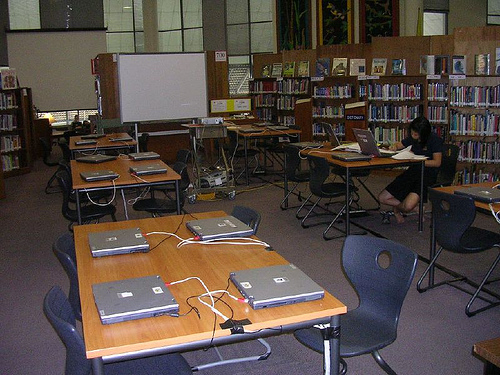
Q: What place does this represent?
A: It represents the library.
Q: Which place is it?
A: It is a library.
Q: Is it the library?
A: Yes, it is the library.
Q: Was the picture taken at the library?
A: Yes, it was taken in the library.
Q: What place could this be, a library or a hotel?
A: It is a library.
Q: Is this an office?
A: No, it is a library.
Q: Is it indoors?
A: Yes, it is indoors.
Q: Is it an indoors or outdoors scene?
A: It is indoors.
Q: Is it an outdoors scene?
A: No, it is indoors.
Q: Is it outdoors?
A: No, it is indoors.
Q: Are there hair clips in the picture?
A: No, there are no hair clips.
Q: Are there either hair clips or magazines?
A: No, there are no hair clips or magazines.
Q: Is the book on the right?
A: Yes, the book is on the right of the image.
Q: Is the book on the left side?
A: No, the book is on the right of the image.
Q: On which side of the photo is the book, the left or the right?
A: The book is on the right of the image.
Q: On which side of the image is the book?
A: The book is on the right of the image.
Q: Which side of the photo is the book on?
A: The book is on the right of the image.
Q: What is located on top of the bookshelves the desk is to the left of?
A: The book is on top of the bookshelves.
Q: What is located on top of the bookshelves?
A: The book is on top of the bookshelves.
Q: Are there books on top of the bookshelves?
A: Yes, there is a book on top of the bookshelves.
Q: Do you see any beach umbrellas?
A: No, there are no beach umbrellas.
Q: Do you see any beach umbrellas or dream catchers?
A: No, there are no beach umbrellas or dream catchers.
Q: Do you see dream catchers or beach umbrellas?
A: No, there are no beach umbrellas or dream catchers.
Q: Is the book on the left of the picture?
A: No, the book is on the right of the image.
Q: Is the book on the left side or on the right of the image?
A: The book is on the right of the image.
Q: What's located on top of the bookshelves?
A: The book is on top of the bookshelves.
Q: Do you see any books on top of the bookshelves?
A: Yes, there is a book on top of the bookshelves.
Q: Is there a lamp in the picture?
A: No, there are no lamps.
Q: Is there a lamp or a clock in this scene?
A: No, there are no lamps or clocks.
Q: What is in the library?
A: The bookshelves are in the library.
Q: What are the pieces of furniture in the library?
A: The pieces of furniture are bookshelves.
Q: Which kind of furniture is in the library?
A: The pieces of furniture are bookshelves.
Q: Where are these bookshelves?
A: The bookshelves are in the library.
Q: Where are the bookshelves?
A: The bookshelves are in the library.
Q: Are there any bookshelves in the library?
A: Yes, there are bookshelves in the library.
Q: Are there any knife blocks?
A: No, there are no knife blocks.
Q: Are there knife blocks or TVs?
A: No, there are no knife blocks or tvs.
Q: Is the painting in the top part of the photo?
A: Yes, the painting is in the top of the image.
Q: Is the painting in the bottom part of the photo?
A: No, the painting is in the top of the image.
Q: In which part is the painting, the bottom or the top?
A: The painting is in the top of the image.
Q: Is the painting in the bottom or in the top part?
A: The painting is in the top of the image.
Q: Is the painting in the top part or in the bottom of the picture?
A: The painting is in the top of the image.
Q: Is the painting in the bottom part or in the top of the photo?
A: The painting is in the top of the image.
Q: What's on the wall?
A: The painting is on the wall.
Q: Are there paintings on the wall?
A: Yes, there is a painting on the wall.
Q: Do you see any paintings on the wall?
A: Yes, there is a painting on the wall.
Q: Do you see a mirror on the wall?
A: No, there is a painting on the wall.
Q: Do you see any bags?
A: No, there are no bags.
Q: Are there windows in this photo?
A: Yes, there is a window.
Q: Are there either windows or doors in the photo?
A: Yes, there is a window.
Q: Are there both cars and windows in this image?
A: No, there is a window but no cars.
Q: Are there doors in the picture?
A: No, there are no doors.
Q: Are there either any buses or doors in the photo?
A: No, there are no doors or buses.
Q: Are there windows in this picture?
A: Yes, there is a window.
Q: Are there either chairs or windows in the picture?
A: Yes, there is a window.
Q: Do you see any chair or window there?
A: Yes, there is a window.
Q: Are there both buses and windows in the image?
A: No, there is a window but no buses.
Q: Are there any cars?
A: No, there are no cars.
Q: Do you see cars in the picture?
A: No, there are no cars.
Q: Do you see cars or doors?
A: No, there are no cars or doors.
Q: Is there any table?
A: Yes, there is a table.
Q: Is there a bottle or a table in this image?
A: Yes, there is a table.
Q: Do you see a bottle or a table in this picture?
A: Yes, there is a table.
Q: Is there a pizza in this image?
A: No, there are no pizzas.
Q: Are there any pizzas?
A: No, there are no pizzas.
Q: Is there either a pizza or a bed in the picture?
A: No, there are no pizzas or beds.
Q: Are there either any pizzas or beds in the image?
A: No, there are no pizzas or beds.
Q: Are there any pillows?
A: No, there are no pillows.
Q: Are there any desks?
A: Yes, there is a desk.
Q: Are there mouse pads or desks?
A: Yes, there is a desk.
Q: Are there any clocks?
A: No, there are no clocks.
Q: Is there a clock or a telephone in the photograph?
A: No, there are no clocks or phones.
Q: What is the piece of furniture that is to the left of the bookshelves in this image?
A: The piece of furniture is a desk.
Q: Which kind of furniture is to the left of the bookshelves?
A: The piece of furniture is a desk.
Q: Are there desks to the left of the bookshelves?
A: Yes, there is a desk to the left of the bookshelves.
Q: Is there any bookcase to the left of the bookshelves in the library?
A: No, there is a desk to the left of the bookshelves.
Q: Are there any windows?
A: Yes, there is a window.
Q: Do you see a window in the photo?
A: Yes, there is a window.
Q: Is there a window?
A: Yes, there is a window.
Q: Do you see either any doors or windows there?
A: Yes, there is a window.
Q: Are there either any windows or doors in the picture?
A: Yes, there is a window.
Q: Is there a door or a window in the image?
A: Yes, there is a window.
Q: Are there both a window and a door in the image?
A: No, there is a window but no doors.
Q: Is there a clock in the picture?
A: No, there are no clocks.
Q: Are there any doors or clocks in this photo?
A: No, there are no clocks or doors.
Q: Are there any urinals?
A: No, there are no urinals.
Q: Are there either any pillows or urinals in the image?
A: No, there are no urinals or pillows.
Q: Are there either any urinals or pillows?
A: No, there are no urinals or pillows.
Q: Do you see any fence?
A: No, there are no fences.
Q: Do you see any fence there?
A: No, there are no fences.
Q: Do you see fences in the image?
A: No, there are no fences.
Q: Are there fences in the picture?
A: No, there are no fences.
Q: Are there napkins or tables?
A: Yes, there is a table.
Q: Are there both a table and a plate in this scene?
A: No, there is a table but no plates.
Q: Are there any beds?
A: No, there are no beds.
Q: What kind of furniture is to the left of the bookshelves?
A: The piece of furniture is a table.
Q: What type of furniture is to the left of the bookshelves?
A: The piece of furniture is a table.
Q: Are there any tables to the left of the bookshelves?
A: Yes, there is a table to the left of the bookshelves.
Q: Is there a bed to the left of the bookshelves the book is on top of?
A: No, there is a table to the left of the bookshelves.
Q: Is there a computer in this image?
A: Yes, there is a computer.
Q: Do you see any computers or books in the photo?
A: Yes, there is a computer.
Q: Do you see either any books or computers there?
A: Yes, there is a computer.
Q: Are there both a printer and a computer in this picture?
A: No, there is a computer but no printers.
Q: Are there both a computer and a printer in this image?
A: No, there is a computer but no printers.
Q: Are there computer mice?
A: No, there are no computer mice.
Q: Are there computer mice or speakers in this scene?
A: No, there are no computer mice or speakers.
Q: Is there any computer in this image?
A: Yes, there is a computer.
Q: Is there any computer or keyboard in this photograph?
A: Yes, there is a computer.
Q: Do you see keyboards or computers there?
A: Yes, there is a computer.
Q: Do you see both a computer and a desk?
A: Yes, there are both a computer and a desk.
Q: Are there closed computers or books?
A: Yes, there is a closed computer.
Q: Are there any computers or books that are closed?
A: Yes, the computer is closed.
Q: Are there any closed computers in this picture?
A: Yes, there is a closed computer.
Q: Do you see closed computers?
A: Yes, there is a closed computer.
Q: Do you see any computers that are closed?
A: Yes, there is a closed computer.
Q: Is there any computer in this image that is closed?
A: Yes, there is a computer that is closed.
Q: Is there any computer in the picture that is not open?
A: Yes, there is an closed computer.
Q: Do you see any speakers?
A: No, there are no speakers.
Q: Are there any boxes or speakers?
A: No, there are no speakers or boxes.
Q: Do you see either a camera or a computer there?
A: Yes, there is a computer.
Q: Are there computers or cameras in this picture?
A: Yes, there is a computer.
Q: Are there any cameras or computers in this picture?
A: Yes, there is a computer.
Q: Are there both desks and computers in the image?
A: Yes, there are both a computer and a desk.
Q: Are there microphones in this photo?
A: No, there are no microphones.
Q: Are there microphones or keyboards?
A: No, there are no microphones or keyboards.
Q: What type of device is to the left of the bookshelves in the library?
A: The device is a computer.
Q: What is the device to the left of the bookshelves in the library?
A: The device is a computer.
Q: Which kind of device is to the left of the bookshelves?
A: The device is a computer.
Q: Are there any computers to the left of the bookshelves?
A: Yes, there is a computer to the left of the bookshelves.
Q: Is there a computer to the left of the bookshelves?
A: Yes, there is a computer to the left of the bookshelves.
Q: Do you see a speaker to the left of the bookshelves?
A: No, there is a computer to the left of the bookshelves.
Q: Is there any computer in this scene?
A: Yes, there is a computer.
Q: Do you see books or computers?
A: Yes, there is a computer.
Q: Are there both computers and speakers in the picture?
A: No, there is a computer but no speakers.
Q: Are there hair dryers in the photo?
A: No, there are no hair dryers.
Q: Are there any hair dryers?
A: No, there are no hair dryers.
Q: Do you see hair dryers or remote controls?
A: No, there are no hair dryers or remote controls.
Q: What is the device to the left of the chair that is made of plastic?
A: The device is a computer.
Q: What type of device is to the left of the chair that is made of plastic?
A: The device is a computer.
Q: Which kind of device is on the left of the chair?
A: The device is a computer.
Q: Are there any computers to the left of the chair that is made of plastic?
A: Yes, there is a computer to the left of the chair.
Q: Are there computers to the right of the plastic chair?
A: No, the computer is to the left of the chair.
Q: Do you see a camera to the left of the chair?
A: No, there is a computer to the left of the chair.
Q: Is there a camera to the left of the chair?
A: No, there is a computer to the left of the chair.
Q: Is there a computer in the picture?
A: Yes, there is a computer.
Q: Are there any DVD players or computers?
A: Yes, there is a computer.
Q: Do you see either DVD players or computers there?
A: Yes, there is a computer.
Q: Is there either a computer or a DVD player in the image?
A: Yes, there is a computer.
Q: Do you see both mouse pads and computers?
A: No, there is a computer but no mouse pads.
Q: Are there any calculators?
A: No, there are no calculators.